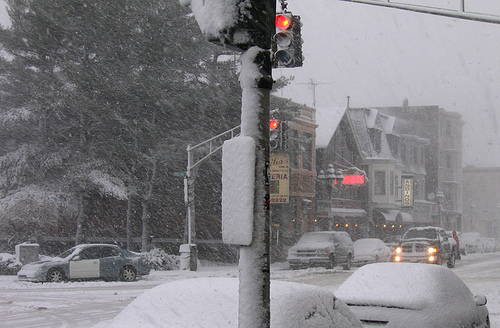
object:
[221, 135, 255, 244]
sign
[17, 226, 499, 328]
car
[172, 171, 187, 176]
road sign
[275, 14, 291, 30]
light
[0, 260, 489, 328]
snow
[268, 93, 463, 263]
building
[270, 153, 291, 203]
sign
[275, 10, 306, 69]
stoplight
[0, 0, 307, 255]
tree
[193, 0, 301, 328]
pole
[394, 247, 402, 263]
headlight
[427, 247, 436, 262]
headlight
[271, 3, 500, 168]
sky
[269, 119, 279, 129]
light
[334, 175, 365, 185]
sign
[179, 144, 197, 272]
pole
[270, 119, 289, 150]
traffic light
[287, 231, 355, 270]
suv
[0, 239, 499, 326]
road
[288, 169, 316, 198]
wall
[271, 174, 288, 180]
lettering